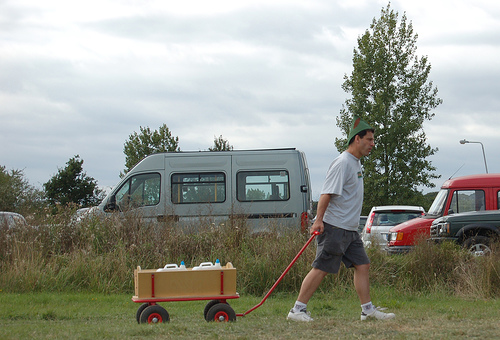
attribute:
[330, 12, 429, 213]
tree — big, green, tall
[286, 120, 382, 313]
man — walking, dressed in gray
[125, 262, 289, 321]
wagon — red, brown, wooden, black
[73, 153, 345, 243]
van — gray, large, facing left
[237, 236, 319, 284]
pole — red, handle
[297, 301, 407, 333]
shoes — tennis shoes, white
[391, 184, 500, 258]
red vehicle — in background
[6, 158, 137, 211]
trees — in background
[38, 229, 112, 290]
grasses — overgrown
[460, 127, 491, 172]
street light — white, tall, in background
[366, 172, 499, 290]
vehicles — in background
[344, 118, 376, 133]
hat — red, green, pointed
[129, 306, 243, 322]
tires — black, red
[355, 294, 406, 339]
left foot — in front of right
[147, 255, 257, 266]
containers — plastic